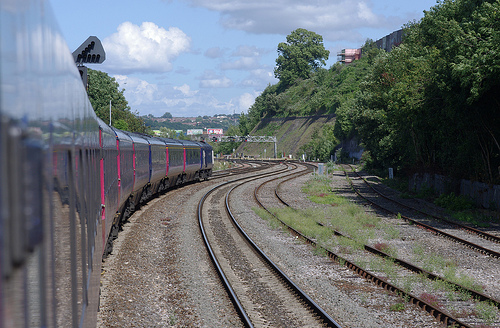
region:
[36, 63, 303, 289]
The train is driving on the tracks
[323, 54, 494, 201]
The trees are green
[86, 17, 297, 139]
The sky is blue and cloudy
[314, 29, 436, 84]
There is a building on the hill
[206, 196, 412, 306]
There is gravel between the tracks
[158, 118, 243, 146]
There are buildings in the distance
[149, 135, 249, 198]
The train is silver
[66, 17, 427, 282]
The weather looks warm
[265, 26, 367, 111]
There is a tree on the hill by the building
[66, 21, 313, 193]
This was taken during the day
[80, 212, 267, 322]
railroad tracks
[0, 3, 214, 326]
part of a train on railroad tracks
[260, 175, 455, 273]
disused sets of railroad tracks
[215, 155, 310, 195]
railroad tracks curve in the distance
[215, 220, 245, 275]
rocks in between set of tracks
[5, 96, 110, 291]
reflection on side of train car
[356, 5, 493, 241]
large trees beside railroad tracks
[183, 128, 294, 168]
metal structure above railroad tracks in the distance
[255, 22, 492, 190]
hill beside tracks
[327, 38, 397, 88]
building on top of hill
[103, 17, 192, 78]
A white fluffy cloud in the sky.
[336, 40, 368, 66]
A house on the top of a hill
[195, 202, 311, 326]
A railroad track on a dirt road.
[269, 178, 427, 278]
Grass growing on a railroad track.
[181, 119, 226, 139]
Colorful billboards on a hill in the distance.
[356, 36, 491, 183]
Green trees and bushes next to a railroad track.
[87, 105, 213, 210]
A silver train on a railroad track.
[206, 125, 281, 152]
Traffic signals for a train.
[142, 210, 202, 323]
Stones filling a railroad track.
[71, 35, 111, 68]
A railroad sign above a train.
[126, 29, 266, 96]
The sky is full of clouds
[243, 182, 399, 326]
The gravel is between the tracks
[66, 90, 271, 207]
The train is on the track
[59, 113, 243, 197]
The train has a lot of cars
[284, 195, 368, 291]
The grass is between the tracks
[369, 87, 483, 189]
Trees are on the side of the tracks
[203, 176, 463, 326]
The tracks are parrallel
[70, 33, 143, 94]
The sign is white and black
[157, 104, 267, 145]
Mountains in the background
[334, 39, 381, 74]
A building on the top of the hill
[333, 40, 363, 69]
Building over looking the tracks on a hillside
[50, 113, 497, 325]
Four sets of rail road tracks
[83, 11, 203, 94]
Fluffy white cloud in the sky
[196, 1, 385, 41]
Fluffy grey cloud in the sky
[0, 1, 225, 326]
Train on railroad tracks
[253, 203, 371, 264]
Grass growing between the rail road tracks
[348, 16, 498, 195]
Trees growing beside the railroad tracks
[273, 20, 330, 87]
Big green tree on the hillside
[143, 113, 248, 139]
City buildings in the background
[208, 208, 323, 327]
Gravel between the train tracks